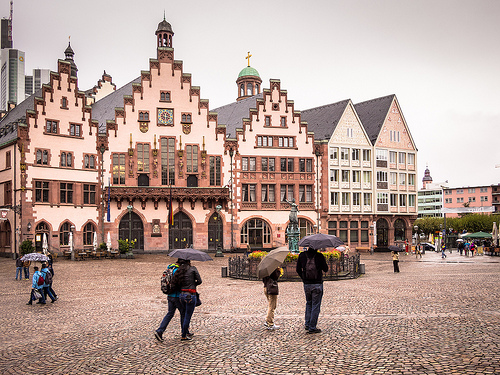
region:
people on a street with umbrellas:
[144, 236, 355, 345]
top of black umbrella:
[161, 244, 212, 265]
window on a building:
[263, 152, 276, 178]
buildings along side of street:
[285, 79, 435, 264]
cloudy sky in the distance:
[412, 69, 487, 166]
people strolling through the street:
[13, 246, 65, 311]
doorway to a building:
[116, 212, 147, 262]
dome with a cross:
[231, 50, 265, 96]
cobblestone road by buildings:
[368, 294, 467, 359]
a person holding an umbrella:
[253, 246, 292, 331]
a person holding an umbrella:
[293, 227, 343, 335]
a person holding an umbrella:
[168, 247, 213, 340]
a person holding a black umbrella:
[294, 231, 348, 338]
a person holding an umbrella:
[19, 251, 49, 306]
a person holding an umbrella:
[387, 244, 402, 271]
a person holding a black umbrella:
[165, 242, 214, 341]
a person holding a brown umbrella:
[254, 245, 292, 333]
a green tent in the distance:
[461, 229, 495, 239]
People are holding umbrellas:
[14, 230, 349, 347]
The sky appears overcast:
[1, 1, 499, 187]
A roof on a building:
[300, 97, 351, 142]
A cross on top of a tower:
[234, 47, 261, 84]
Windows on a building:
[253, 132, 297, 152]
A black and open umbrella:
[297, 228, 346, 251]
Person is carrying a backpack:
[290, 241, 332, 284]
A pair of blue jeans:
[175, 288, 198, 338]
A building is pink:
[440, 182, 494, 215]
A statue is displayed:
[278, 193, 303, 253]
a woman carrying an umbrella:
[166, 239, 216, 347]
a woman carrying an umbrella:
[253, 239, 291, 335]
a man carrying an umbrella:
[292, 226, 343, 335]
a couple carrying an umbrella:
[16, 246, 60, 311]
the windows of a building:
[33, 145, 56, 168]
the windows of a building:
[57, 148, 78, 173]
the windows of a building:
[80, 150, 99, 172]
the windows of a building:
[157, 131, 177, 185]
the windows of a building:
[238, 153, 259, 180]